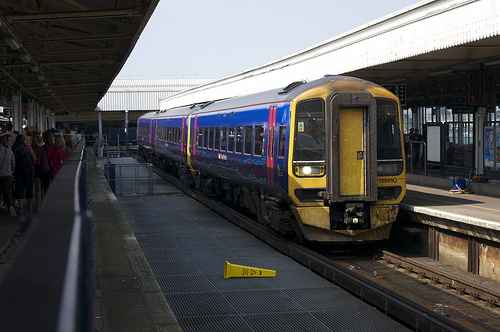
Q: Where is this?
A: This is at the train station.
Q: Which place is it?
A: It is a train station.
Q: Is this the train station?
A: Yes, it is the train station.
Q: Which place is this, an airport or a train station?
A: It is a train station.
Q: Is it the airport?
A: No, it is the train station.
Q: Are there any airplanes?
A: No, there are no airplanes.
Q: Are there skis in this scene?
A: No, there are no skis.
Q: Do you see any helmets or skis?
A: No, there are no skis or helmets.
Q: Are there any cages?
A: No, there are no cages.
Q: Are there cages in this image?
A: No, there are no cages.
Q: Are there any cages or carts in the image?
A: No, there are no cages or carts.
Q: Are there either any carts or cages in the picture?
A: No, there are no cages or carts.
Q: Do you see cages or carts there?
A: No, there are no cages or carts.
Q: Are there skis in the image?
A: No, there are no skis.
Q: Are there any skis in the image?
A: No, there are no skis.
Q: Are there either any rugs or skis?
A: No, there are no skis or rugs.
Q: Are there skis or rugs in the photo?
A: No, there are no skis or rugs.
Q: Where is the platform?
A: The platform is at the train station.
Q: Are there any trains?
A: Yes, there is a train.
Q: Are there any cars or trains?
A: Yes, there is a train.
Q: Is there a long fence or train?
A: Yes, there is a long train.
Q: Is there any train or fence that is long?
A: Yes, the train is long.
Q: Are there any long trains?
A: Yes, there is a long train.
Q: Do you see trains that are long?
A: Yes, there is a train that is long.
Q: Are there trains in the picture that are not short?
A: Yes, there is a long train.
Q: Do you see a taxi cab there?
A: No, there are no taxis.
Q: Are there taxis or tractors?
A: No, there are no taxis or tractors.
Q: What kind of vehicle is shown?
A: The vehicle is a train.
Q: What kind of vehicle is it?
A: The vehicle is a train.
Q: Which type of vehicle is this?
A: This is a train.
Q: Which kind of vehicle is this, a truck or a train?
A: This is a train.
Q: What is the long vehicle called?
A: The vehicle is a train.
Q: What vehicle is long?
A: The vehicle is a train.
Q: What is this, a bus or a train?
A: This is a train.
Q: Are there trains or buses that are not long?
A: No, there is a train but it is long.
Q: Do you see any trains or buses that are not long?
A: No, there is a train but it is long.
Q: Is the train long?
A: Yes, the train is long.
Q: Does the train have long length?
A: Yes, the train is long.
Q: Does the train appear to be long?
A: Yes, the train is long.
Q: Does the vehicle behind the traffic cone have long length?
A: Yes, the train is long.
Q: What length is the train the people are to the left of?
A: The train is long.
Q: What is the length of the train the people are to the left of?
A: The train is long.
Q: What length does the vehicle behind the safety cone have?
A: The train has long length.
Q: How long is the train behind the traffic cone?
A: The train is long.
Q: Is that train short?
A: No, the train is long.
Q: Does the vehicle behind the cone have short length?
A: No, the train is long.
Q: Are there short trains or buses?
A: No, there is a train but it is long.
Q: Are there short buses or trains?
A: No, there is a train but it is long.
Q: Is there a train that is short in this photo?
A: No, there is a train but it is long.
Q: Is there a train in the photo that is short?
A: No, there is a train but it is long.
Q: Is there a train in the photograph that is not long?
A: No, there is a train but it is long.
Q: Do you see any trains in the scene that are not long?
A: No, there is a train but it is long.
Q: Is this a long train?
A: Yes, this is a long train.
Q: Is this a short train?
A: No, this is a long train.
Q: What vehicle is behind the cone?
A: The vehicle is a train.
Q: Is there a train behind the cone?
A: Yes, there is a train behind the cone.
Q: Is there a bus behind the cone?
A: No, there is a train behind the cone.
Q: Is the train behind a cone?
A: Yes, the train is behind a cone.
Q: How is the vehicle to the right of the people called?
A: The vehicle is a train.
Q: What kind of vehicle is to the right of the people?
A: The vehicle is a train.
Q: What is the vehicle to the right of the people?
A: The vehicle is a train.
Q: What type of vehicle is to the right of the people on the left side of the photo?
A: The vehicle is a train.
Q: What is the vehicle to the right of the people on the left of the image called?
A: The vehicle is a train.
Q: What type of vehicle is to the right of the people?
A: The vehicle is a train.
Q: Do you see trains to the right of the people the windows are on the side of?
A: Yes, there is a train to the right of the people.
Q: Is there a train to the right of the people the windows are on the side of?
A: Yes, there is a train to the right of the people.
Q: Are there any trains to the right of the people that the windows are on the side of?
A: Yes, there is a train to the right of the people.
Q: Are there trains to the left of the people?
A: No, the train is to the right of the people.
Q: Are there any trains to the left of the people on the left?
A: No, the train is to the right of the people.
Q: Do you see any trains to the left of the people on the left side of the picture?
A: No, the train is to the right of the people.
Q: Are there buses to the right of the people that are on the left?
A: No, there is a train to the right of the people.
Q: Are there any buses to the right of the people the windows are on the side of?
A: No, there is a train to the right of the people.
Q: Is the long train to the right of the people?
A: Yes, the train is to the right of the people.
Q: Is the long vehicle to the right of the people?
A: Yes, the train is to the right of the people.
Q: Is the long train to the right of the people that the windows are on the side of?
A: Yes, the train is to the right of the people.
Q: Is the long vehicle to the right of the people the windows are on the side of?
A: Yes, the train is to the right of the people.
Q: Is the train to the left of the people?
A: No, the train is to the right of the people.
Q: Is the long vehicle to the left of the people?
A: No, the train is to the right of the people.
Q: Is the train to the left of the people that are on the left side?
A: No, the train is to the right of the people.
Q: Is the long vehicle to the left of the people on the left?
A: No, the train is to the right of the people.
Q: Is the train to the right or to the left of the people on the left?
A: The train is to the right of the people.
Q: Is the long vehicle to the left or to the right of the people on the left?
A: The train is to the right of the people.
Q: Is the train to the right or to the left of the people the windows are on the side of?
A: The train is to the right of the people.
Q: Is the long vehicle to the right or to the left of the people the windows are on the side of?
A: The train is to the right of the people.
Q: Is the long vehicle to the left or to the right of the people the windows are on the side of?
A: The train is to the right of the people.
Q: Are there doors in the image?
A: Yes, there is a door.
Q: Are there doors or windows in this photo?
A: Yes, there is a door.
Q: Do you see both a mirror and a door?
A: No, there is a door but no mirrors.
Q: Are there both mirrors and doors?
A: No, there is a door but no mirrors.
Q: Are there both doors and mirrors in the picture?
A: No, there is a door but no mirrors.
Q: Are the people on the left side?
A: Yes, the people are on the left of the image.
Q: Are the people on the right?
A: No, the people are on the left of the image.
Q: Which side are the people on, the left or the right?
A: The people are on the left of the image.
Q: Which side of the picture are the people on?
A: The people are on the left of the image.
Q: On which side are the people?
A: The people are on the left of the image.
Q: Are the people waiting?
A: Yes, the people are waiting.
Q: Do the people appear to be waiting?
A: Yes, the people are waiting.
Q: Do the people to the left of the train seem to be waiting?
A: Yes, the people are waiting.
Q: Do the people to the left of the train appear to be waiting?
A: Yes, the people are waiting.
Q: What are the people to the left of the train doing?
A: The people are waiting.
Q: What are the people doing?
A: The people are waiting.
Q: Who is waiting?
A: The people are waiting.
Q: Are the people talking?
A: No, the people are waiting.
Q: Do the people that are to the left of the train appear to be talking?
A: No, the people are waiting.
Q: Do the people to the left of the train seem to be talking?
A: No, the people are waiting.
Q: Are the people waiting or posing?
A: The people are waiting.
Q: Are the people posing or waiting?
A: The people are waiting.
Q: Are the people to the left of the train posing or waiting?
A: The people are waiting.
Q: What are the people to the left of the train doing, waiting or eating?
A: The people are waiting.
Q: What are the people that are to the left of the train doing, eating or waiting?
A: The people are waiting.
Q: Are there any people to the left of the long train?
A: Yes, there are people to the left of the train.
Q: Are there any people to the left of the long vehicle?
A: Yes, there are people to the left of the train.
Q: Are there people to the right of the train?
A: No, the people are to the left of the train.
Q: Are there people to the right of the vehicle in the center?
A: No, the people are to the left of the train.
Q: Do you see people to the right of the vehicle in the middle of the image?
A: No, the people are to the left of the train.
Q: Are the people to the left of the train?
A: Yes, the people are to the left of the train.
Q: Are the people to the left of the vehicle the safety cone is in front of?
A: Yes, the people are to the left of the train.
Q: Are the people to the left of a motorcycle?
A: No, the people are to the left of the train.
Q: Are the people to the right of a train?
A: No, the people are to the left of a train.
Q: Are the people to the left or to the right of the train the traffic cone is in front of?
A: The people are to the left of the train.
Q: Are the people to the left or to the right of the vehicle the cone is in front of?
A: The people are to the left of the train.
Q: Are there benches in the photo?
A: No, there are no benches.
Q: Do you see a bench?
A: No, there are no benches.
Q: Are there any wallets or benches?
A: No, there are no benches or wallets.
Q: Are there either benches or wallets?
A: No, there are no benches or wallets.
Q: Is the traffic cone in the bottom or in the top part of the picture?
A: The traffic cone is in the bottom of the image.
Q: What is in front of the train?
A: The traffic cone is in front of the train.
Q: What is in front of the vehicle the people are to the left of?
A: The traffic cone is in front of the train.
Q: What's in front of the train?
A: The traffic cone is in front of the train.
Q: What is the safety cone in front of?
A: The safety cone is in front of the train.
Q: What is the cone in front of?
A: The safety cone is in front of the train.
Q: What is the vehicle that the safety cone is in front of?
A: The vehicle is a train.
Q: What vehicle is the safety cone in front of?
A: The safety cone is in front of the train.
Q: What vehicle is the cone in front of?
A: The safety cone is in front of the train.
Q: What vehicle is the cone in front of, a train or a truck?
A: The cone is in front of a train.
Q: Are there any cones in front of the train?
A: Yes, there is a cone in front of the train.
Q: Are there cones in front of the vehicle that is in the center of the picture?
A: Yes, there is a cone in front of the train.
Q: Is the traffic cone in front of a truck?
A: No, the traffic cone is in front of the train.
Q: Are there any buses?
A: No, there are no buses.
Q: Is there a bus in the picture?
A: No, there are no buses.